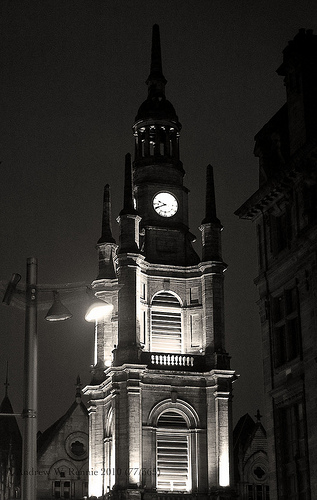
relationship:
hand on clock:
[153, 204, 166, 210] [152, 190, 180, 217]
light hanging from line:
[45, 293, 71, 328] [31, 274, 81, 296]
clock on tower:
[151, 188, 179, 218] [73, 16, 245, 495]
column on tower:
[143, 130, 151, 161] [73, 16, 245, 495]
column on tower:
[132, 127, 143, 150] [131, 129, 144, 147]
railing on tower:
[145, 350, 207, 367] [80, 19, 242, 499]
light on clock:
[149, 185, 181, 221] [133, 173, 199, 229]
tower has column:
[73, 16, 245, 495] [200, 260, 225, 352]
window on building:
[52, 477, 75, 498] [35, 372, 90, 496]